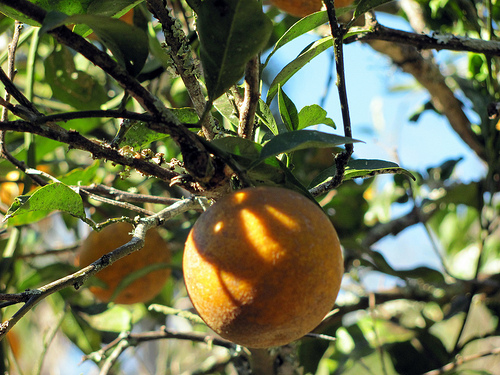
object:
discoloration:
[121, 237, 169, 297]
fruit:
[78, 220, 169, 304]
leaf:
[116, 109, 201, 152]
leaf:
[4, 182, 91, 227]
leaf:
[110, 105, 206, 151]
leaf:
[196, 2, 276, 63]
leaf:
[273, 81, 305, 131]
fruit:
[271, 0, 351, 15]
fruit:
[66, 9, 135, 39]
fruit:
[0, 169, 27, 211]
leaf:
[263, 7, 371, 73]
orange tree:
[2, 0, 499, 374]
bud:
[156, 152, 168, 165]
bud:
[138, 146, 154, 162]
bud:
[167, 156, 182, 171]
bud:
[120, 143, 135, 157]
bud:
[70, 280, 85, 292]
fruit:
[183, 191, 345, 351]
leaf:
[196, 2, 276, 128]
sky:
[270, 12, 487, 183]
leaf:
[330, 153, 425, 185]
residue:
[365, 168, 383, 178]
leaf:
[34, 4, 156, 88]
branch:
[314, 2, 356, 198]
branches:
[5, 2, 277, 184]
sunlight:
[190, 272, 235, 297]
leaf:
[267, 87, 297, 142]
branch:
[0, 180, 198, 324]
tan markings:
[201, 214, 327, 351]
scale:
[204, 17, 245, 85]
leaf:
[246, 128, 372, 160]